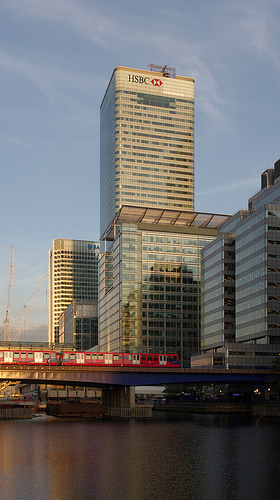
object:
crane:
[0, 271, 49, 350]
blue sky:
[0, 0, 280, 331]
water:
[0, 413, 280, 500]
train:
[0, 348, 181, 371]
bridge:
[0, 358, 280, 419]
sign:
[150, 78, 164, 87]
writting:
[127, 73, 149, 87]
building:
[47, 236, 99, 352]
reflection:
[0, 413, 280, 500]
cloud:
[0, 0, 280, 328]